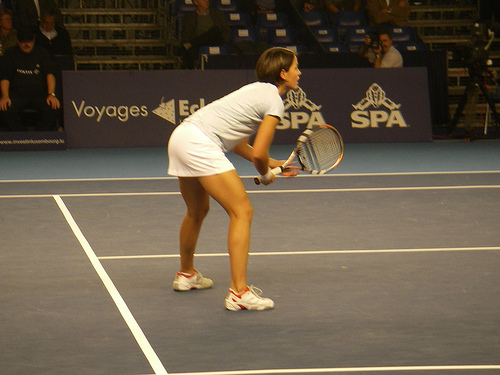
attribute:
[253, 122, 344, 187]
tennis racket — orange and white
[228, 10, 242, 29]
empty chair — blue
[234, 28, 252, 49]
empty chair — blue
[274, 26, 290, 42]
empty chair — blue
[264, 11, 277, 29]
empty chair — blue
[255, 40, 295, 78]
hair — brown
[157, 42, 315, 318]
woman — tennis player